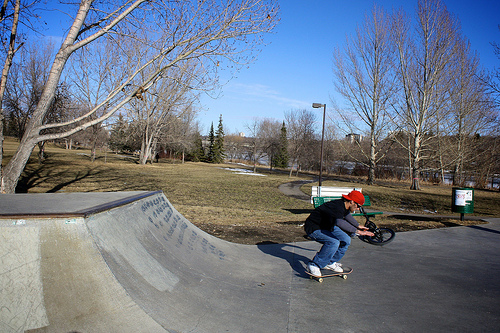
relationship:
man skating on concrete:
[294, 193, 376, 310] [183, 261, 268, 302]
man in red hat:
[294, 193, 376, 310] [347, 186, 360, 208]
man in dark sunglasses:
[294, 193, 376, 310] [357, 202, 362, 214]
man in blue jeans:
[294, 193, 376, 310] [308, 228, 349, 262]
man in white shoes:
[294, 193, 376, 310] [298, 263, 354, 271]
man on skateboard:
[294, 193, 376, 310] [312, 267, 360, 276]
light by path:
[311, 98, 334, 192] [279, 179, 305, 202]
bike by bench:
[360, 207, 407, 242] [315, 196, 323, 208]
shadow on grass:
[36, 168, 96, 193] [162, 182, 203, 190]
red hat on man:
[347, 186, 360, 208] [294, 193, 376, 310]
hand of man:
[357, 221, 369, 241] [294, 193, 376, 310]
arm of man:
[331, 214, 360, 231] [294, 193, 376, 310]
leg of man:
[322, 232, 339, 262] [294, 193, 376, 310]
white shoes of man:
[298, 263, 354, 271] [294, 193, 376, 310]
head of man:
[346, 199, 363, 213] [294, 193, 376, 310]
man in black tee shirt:
[294, 193, 376, 310] [308, 202, 339, 233]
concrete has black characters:
[183, 261, 268, 302] [146, 203, 212, 256]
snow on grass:
[223, 165, 262, 181] [162, 182, 203, 190]